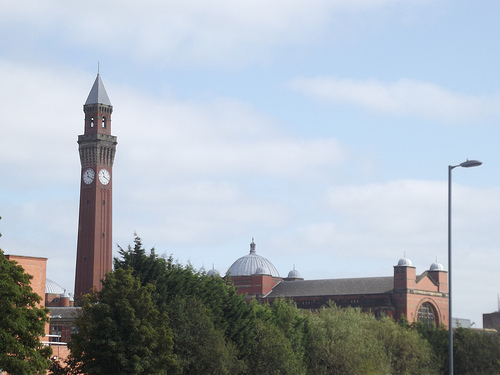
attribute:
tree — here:
[4, 241, 67, 374]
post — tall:
[440, 161, 486, 374]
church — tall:
[68, 60, 449, 350]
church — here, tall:
[73, 58, 119, 312]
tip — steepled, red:
[79, 57, 114, 108]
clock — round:
[78, 167, 95, 186]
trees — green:
[3, 251, 499, 370]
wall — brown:
[3, 250, 54, 372]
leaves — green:
[3, 242, 496, 373]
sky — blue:
[131, 17, 486, 148]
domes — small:
[223, 239, 448, 281]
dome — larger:
[217, 239, 279, 278]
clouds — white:
[127, 10, 490, 150]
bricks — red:
[393, 278, 442, 307]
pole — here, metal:
[442, 160, 468, 373]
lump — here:
[225, 235, 277, 277]